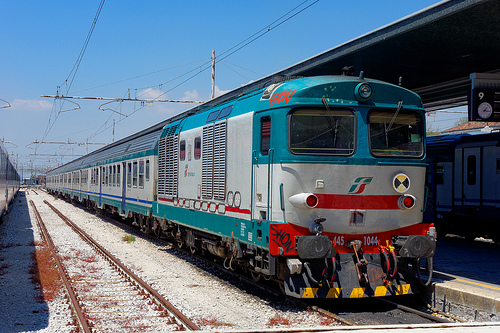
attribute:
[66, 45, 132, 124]
lines — suspended, yellow, overhead, long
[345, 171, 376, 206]
logo — red, blue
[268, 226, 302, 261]
graffiti — red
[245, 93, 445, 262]
train — teal, blue, gray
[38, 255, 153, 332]
tracks — straight, parallel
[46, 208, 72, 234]
gravel — white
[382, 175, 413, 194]
valves — intake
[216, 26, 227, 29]
sky — blue, cloudy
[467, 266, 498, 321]
platform — 9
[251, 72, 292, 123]
roof — blue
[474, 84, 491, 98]
number — 9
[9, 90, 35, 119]
clouds — fluffy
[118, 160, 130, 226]
door — blue